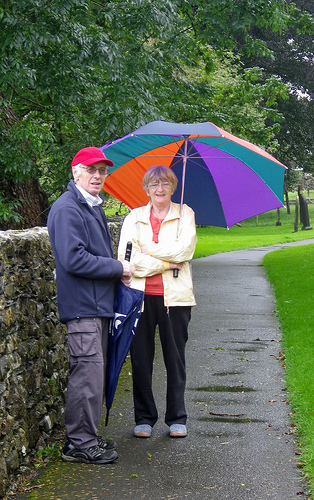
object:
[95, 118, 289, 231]
umbrella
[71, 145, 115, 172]
hat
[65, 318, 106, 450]
pants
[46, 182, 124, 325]
jacket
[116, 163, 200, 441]
woman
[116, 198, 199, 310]
yellow top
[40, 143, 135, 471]
man